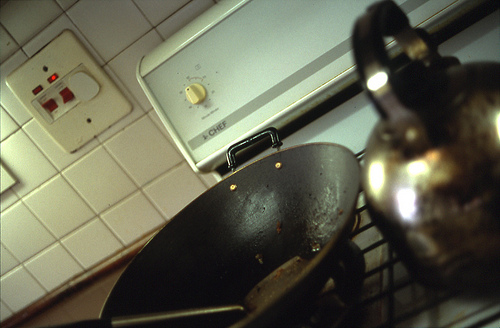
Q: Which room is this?
A: It is a kitchen.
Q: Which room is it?
A: It is a kitchen.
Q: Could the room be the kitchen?
A: Yes, it is the kitchen.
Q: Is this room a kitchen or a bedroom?
A: It is a kitchen.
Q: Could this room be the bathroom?
A: No, it is the kitchen.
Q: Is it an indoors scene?
A: Yes, it is indoors.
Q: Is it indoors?
A: Yes, it is indoors.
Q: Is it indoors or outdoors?
A: It is indoors.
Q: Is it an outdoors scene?
A: No, it is indoors.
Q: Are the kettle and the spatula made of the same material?
A: Yes, both the kettle and the spatula are made of metal.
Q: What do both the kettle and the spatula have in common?
A: The material, both the kettle and the spatula are metallic.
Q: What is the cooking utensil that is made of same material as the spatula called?
A: The cooking utensil is a kettle.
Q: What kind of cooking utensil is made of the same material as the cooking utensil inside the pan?
A: The kettle is made of the same material as the spatula.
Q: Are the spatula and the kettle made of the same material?
A: Yes, both the spatula and the kettle are made of metal.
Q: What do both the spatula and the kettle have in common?
A: The material, both the spatula and the kettle are metallic.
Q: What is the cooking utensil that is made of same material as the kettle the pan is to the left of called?
A: The cooking utensil is a spatula.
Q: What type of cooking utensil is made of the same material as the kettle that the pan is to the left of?
A: The spatula is made of the same material as the kettle.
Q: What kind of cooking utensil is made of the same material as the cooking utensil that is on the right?
A: The spatula is made of the same material as the kettle.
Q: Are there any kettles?
A: Yes, there is a kettle.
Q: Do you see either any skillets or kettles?
A: Yes, there is a kettle.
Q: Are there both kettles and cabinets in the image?
A: No, there is a kettle but no cabinets.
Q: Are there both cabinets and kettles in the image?
A: No, there is a kettle but no cabinets.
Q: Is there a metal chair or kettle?
A: Yes, there is a metal kettle.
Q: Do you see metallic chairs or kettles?
A: Yes, there is a metal kettle.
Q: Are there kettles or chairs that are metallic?
A: Yes, the kettle is metallic.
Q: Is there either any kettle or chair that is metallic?
A: Yes, the kettle is metallic.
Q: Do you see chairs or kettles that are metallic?
A: Yes, the kettle is metallic.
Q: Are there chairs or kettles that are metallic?
A: Yes, the kettle is metallic.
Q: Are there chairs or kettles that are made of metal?
A: Yes, the kettle is made of metal.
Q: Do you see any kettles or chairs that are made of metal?
A: Yes, the kettle is made of metal.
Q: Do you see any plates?
A: No, there are no plates.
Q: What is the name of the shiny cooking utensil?
A: The cooking utensil is a kettle.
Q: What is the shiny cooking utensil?
A: The cooking utensil is a kettle.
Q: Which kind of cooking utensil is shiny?
A: The cooking utensil is a kettle.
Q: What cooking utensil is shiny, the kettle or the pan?
A: The kettle is shiny.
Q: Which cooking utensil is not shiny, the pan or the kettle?
A: The pan is not shiny.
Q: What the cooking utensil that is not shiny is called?
A: The cooking utensil is a pan.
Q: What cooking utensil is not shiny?
A: The cooking utensil is a pan.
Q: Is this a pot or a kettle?
A: This is a kettle.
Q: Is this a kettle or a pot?
A: This is a kettle.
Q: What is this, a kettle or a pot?
A: This is a kettle.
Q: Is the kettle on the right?
A: Yes, the kettle is on the right of the image.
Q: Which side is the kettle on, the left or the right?
A: The kettle is on the right of the image.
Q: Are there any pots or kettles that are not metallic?
A: No, there is a kettle but it is metallic.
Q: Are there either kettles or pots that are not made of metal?
A: No, there is a kettle but it is made of metal.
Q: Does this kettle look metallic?
A: Yes, the kettle is metallic.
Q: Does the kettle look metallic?
A: Yes, the kettle is metallic.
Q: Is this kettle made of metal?
A: Yes, the kettle is made of metal.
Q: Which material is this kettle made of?
A: The kettle is made of metal.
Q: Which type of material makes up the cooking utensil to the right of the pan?
A: The kettle is made of metal.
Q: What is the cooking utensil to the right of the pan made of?
A: The kettle is made of metal.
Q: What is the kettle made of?
A: The kettle is made of metal.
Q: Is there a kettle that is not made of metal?
A: No, there is a kettle but it is made of metal.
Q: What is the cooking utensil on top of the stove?
A: The cooking utensil is a kettle.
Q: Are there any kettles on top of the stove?
A: Yes, there is a kettle on top of the stove.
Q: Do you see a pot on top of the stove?
A: No, there is a kettle on top of the stove.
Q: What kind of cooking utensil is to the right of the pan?
A: The cooking utensil is a kettle.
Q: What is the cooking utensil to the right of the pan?
A: The cooking utensil is a kettle.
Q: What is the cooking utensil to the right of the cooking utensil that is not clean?
A: The cooking utensil is a kettle.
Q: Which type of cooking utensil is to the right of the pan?
A: The cooking utensil is a kettle.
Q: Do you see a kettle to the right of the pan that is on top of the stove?
A: Yes, there is a kettle to the right of the pan.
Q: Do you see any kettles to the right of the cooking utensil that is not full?
A: Yes, there is a kettle to the right of the pan.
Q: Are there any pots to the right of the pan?
A: No, there is a kettle to the right of the pan.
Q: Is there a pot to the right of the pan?
A: No, there is a kettle to the right of the pan.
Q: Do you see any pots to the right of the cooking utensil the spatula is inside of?
A: No, there is a kettle to the right of the pan.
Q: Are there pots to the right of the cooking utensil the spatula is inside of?
A: No, there is a kettle to the right of the pan.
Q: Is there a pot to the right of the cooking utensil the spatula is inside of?
A: No, there is a kettle to the right of the pan.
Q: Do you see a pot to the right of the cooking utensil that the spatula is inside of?
A: No, there is a kettle to the right of the pan.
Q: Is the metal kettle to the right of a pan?
A: Yes, the kettle is to the right of a pan.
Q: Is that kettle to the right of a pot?
A: No, the kettle is to the right of a pan.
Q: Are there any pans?
A: Yes, there is a pan.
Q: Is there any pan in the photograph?
A: Yes, there is a pan.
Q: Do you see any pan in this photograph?
A: Yes, there is a pan.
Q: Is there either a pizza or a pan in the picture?
A: Yes, there is a pan.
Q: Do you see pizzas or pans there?
A: Yes, there is a pan.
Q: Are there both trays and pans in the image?
A: No, there is a pan but no trays.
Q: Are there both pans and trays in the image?
A: No, there is a pan but no trays.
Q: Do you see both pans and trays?
A: No, there is a pan but no trays.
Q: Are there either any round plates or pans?
A: Yes, there is a round pan.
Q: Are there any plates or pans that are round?
A: Yes, the pan is round.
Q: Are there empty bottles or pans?
A: Yes, there is an empty pan.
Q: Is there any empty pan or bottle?
A: Yes, there is an empty pan.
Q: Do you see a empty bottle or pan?
A: Yes, there is an empty pan.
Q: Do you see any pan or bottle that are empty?
A: Yes, the pan is empty.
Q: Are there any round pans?
A: Yes, there is a round pan.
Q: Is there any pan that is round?
A: Yes, there is a pan that is round.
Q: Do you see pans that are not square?
A: Yes, there is a round pan.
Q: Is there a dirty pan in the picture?
A: Yes, there is a dirty pan.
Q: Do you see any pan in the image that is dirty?
A: Yes, there is a pan that is dirty.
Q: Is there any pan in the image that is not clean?
A: Yes, there is a dirty pan.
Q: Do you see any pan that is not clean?
A: Yes, there is a dirty pan.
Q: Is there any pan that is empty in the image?
A: Yes, there is an empty pan.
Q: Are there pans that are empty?
A: Yes, there is a pan that is empty.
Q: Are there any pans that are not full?
A: Yes, there is a empty pan.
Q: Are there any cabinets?
A: No, there are no cabinets.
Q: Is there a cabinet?
A: No, there are no cabinets.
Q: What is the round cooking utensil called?
A: The cooking utensil is a pan.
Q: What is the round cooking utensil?
A: The cooking utensil is a pan.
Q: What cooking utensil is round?
A: The cooking utensil is a pan.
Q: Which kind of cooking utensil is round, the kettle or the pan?
A: The pan is round.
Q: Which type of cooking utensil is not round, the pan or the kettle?
A: The kettle is not round.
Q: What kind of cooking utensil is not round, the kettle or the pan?
A: The kettle is not round.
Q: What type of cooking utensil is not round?
A: The cooking utensil is a kettle.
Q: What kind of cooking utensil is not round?
A: The cooking utensil is a kettle.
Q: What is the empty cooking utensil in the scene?
A: The cooking utensil is a pan.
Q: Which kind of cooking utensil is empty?
A: The cooking utensil is a pan.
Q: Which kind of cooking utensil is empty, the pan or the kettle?
A: The pan is empty.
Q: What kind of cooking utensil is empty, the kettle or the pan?
A: The pan is empty.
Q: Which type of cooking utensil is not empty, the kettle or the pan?
A: The kettle is not empty.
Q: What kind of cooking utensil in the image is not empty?
A: The cooking utensil is a kettle.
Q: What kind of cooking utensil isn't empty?
A: The cooking utensil is a kettle.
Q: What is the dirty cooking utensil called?
A: The cooking utensil is a pan.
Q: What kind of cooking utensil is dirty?
A: The cooking utensil is a pan.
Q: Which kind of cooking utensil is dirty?
A: The cooking utensil is a pan.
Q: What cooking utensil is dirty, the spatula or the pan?
A: The pan is dirty.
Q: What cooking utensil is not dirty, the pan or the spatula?
A: The spatula is not dirty.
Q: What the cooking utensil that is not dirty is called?
A: The cooking utensil is a spatula.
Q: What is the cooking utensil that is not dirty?
A: The cooking utensil is a spatula.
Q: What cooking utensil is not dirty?
A: The cooking utensil is a spatula.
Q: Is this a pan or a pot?
A: This is a pan.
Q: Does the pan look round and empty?
A: Yes, the pan is round and empty.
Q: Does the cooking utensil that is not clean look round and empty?
A: Yes, the pan is round and empty.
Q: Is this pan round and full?
A: No, the pan is round but empty.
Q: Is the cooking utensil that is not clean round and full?
A: No, the pan is round but empty.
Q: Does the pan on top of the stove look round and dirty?
A: Yes, the pan is round and dirty.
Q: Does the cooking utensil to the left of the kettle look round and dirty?
A: Yes, the pan is round and dirty.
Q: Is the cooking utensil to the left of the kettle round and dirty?
A: Yes, the pan is round and dirty.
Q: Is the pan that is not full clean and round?
A: No, the pan is round but dirty.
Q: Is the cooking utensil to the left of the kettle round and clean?
A: No, the pan is round but dirty.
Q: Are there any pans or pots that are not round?
A: No, there is a pan but it is round.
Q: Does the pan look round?
A: Yes, the pan is round.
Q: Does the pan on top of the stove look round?
A: Yes, the pan is round.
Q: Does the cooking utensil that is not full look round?
A: Yes, the pan is round.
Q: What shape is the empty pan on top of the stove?
A: The pan is round.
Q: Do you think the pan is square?
A: No, the pan is round.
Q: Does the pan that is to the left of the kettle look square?
A: No, the pan is round.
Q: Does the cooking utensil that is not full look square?
A: No, the pan is round.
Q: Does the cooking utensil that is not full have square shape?
A: No, the pan is round.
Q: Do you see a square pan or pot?
A: No, there is a pan but it is round.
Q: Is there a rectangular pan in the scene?
A: No, there is a pan but it is round.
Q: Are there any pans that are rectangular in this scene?
A: No, there is a pan but it is round.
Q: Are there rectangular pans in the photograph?
A: No, there is a pan but it is round.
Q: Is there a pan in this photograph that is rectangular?
A: No, there is a pan but it is round.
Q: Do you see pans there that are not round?
A: No, there is a pan but it is round.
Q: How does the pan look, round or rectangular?
A: The pan is round.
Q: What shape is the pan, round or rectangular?
A: The pan is round.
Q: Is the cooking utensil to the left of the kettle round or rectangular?
A: The pan is round.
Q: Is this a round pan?
A: Yes, this is a round pan.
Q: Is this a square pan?
A: No, this is a round pan.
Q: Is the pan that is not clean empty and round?
A: Yes, the pan is empty and round.